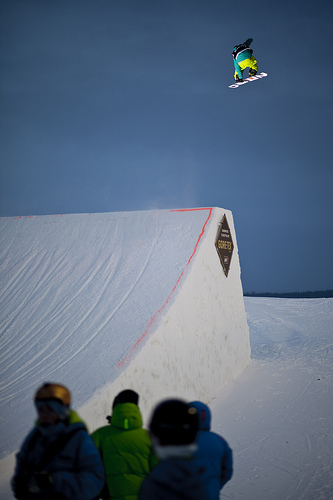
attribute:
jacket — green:
[89, 402, 145, 497]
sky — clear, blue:
[1, 36, 332, 298]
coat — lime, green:
[96, 386, 149, 498]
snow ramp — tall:
[8, 206, 253, 386]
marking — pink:
[164, 201, 213, 294]